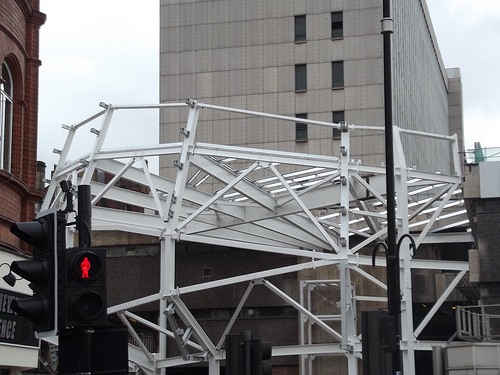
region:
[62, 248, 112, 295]
Red image of a person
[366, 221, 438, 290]
Two black upside down hooks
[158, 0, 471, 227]
Gray building with six windows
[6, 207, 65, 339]
Traffic signal painted black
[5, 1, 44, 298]
Red brick building with arched window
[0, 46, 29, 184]
Arched window of brick building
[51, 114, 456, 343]
White metal pieces hooked together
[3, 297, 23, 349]
White letters on black board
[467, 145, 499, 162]
Fence on top of building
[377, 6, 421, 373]
Long black pole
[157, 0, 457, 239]
a multi story building.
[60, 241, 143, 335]
a cross walk signal.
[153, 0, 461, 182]
a very tall building.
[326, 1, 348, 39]
a window on the side of a building.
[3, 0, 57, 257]
a tall brown building.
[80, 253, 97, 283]
a small red person.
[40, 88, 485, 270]
a metal scaffolding.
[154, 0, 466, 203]
a tall multi story building.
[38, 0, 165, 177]
a cloudy gray sky.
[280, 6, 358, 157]
6 windows in the picture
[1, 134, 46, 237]
building made of bricks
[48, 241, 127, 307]
person in red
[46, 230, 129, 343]
pedestrian stop light here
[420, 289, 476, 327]
light are here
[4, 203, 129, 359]
traffic signals are present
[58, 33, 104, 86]
the sky is cloudy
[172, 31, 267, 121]
no windows are present here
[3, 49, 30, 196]
window on a building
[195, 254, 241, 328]
small windows on the building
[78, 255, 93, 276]
a red man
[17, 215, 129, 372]
the lights are black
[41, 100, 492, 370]
a white metal structure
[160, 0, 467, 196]
the building has many windows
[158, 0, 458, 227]
the building is gray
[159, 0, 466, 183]
the building has square design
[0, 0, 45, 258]
the side building is made of brick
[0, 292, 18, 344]
a sign has letters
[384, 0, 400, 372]
a black pole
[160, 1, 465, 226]
a tall building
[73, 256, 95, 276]
A red light of a man.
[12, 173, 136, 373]
A traffic light.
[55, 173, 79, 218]
A traffic camera on the light.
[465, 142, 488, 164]
A sign on the building.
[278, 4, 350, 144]
A row of windows.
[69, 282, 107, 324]
A light is off.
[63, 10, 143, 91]
the sky is overcast.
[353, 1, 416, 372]
A post is tall.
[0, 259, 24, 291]
A light on the building.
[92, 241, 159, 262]
Another row of windows.